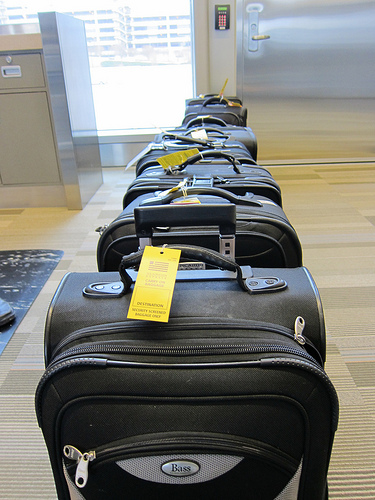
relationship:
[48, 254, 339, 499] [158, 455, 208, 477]
suitcase says bass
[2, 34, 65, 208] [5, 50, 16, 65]
drawer can lock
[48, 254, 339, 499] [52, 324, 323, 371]
suitcase has zipper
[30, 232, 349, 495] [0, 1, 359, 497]
suitcases in airport